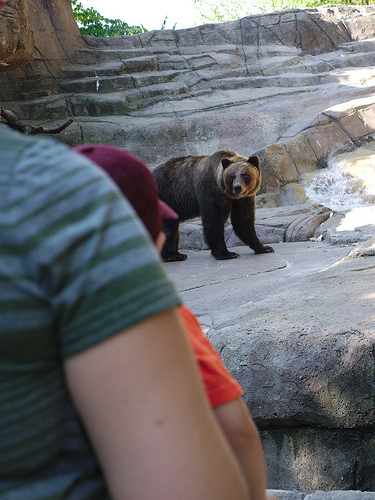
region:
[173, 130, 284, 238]
bear on the ground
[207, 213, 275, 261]
legs of the bear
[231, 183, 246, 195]
nose of the bear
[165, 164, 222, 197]
brown fur of the bear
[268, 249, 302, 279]
gray ground in front of bear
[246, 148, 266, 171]
ear of the bear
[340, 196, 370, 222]
light hitting the ground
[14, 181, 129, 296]
shirt on the person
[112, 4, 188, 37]
light in the background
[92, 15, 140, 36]
green leaves in the background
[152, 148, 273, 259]
brown and black bear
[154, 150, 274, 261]
bear standing on rock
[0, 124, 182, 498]
green and blue shirt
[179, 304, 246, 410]
orange cotton tee shirt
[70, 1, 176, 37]
tree with green leaves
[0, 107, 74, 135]
brown branch on rocks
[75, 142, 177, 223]
maroon baseball cap on head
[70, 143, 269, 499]
boy wearing orange shirt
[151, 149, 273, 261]
bear in zoo exhibit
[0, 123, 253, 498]
person holding boy in lap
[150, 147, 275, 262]
A bear at the zoo.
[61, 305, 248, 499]
Part of a women's arm.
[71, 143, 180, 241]
Part of a hat.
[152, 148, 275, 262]
A big brown bear.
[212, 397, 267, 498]
Part of a boy's arm.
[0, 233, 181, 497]
Part of a tshirt.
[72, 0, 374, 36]
Trees behind some rocks.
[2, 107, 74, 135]
A stick on rocks.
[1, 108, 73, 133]
A branch on rocks.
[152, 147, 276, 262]
A bear on rocks.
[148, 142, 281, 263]
A big brown bear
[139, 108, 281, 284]
A big brown bear standing on rocks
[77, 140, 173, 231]
A burgundy baseball cap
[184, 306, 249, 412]
Orange tee shirt on arm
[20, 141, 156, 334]
Blue and green tee shirt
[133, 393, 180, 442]
A spot on an arm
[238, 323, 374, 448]
The edge of the rock cliff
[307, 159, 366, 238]
Rapid running water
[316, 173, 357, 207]
White foam on the water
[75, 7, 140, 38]
Green bushes at the top of the rocks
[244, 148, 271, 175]
Bear has brown ear.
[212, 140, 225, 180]
Bear has brown ear.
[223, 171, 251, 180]
Bear has dark eyes.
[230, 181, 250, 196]
Bear has black nose.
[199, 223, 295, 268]
Bear has black paws.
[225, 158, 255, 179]
Bear has brown nose.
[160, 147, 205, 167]
Bear has brown fur on back.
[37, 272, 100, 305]
Person wearing gray shirt.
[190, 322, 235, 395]
Person wearing orange shirt.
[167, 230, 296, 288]
Bear standing on rocky ground.